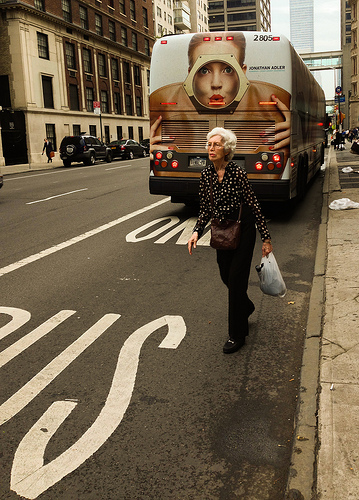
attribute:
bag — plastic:
[256, 250, 286, 298]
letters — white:
[0, 300, 194, 496]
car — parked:
[59, 135, 113, 165]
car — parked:
[107, 138, 147, 159]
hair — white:
[205, 125, 237, 162]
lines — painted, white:
[0, 188, 173, 293]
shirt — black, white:
[168, 161, 284, 253]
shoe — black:
[221, 331, 246, 352]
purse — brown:
[207, 203, 242, 251]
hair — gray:
[204, 123, 237, 159]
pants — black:
[212, 224, 257, 339]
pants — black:
[216, 215, 256, 335]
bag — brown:
[207, 201, 242, 250]